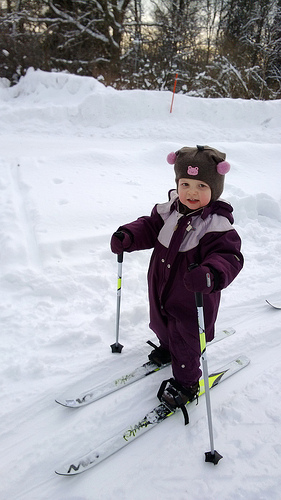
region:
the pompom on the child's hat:
[216, 161, 230, 175]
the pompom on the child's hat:
[166, 151, 176, 165]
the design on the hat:
[186, 164, 198, 174]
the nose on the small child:
[187, 187, 197, 196]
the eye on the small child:
[179, 181, 188, 186]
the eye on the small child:
[197, 183, 206, 187]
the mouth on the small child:
[186, 197, 198, 203]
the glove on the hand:
[182, 264, 213, 292]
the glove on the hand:
[109, 228, 129, 254]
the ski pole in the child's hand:
[189, 263, 222, 465]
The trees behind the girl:
[10, 0, 271, 97]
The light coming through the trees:
[111, 1, 241, 57]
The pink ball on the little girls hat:
[214, 155, 230, 172]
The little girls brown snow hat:
[164, 145, 234, 191]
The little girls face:
[182, 174, 212, 207]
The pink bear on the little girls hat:
[182, 165, 204, 179]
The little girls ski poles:
[190, 263, 231, 465]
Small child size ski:
[42, 306, 257, 472]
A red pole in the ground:
[169, 70, 181, 122]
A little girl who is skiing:
[31, 149, 255, 495]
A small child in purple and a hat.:
[109, 145, 244, 406]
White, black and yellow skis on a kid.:
[47, 325, 250, 475]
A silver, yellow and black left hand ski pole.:
[188, 260, 222, 465]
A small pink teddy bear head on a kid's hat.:
[188, 164, 200, 175]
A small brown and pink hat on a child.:
[165, 143, 230, 205]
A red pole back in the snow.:
[169, 70, 179, 113]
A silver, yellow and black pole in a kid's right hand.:
[109, 231, 124, 353]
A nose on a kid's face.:
[187, 183, 198, 195]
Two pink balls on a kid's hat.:
[166, 152, 229, 176]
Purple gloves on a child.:
[111, 230, 212, 292]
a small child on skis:
[54, 144, 248, 475]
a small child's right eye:
[181, 181, 191, 189]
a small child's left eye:
[196, 182, 206, 190]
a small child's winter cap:
[167, 142, 228, 202]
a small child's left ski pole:
[191, 263, 223, 467]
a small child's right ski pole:
[106, 234, 126, 351]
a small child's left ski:
[54, 353, 249, 476]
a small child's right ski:
[54, 325, 233, 410]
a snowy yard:
[0, 67, 280, 498]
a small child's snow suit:
[123, 188, 244, 382]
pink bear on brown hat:
[185, 165, 199, 176]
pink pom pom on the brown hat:
[214, 162, 230, 175]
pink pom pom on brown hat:
[164, 151, 176, 163]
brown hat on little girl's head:
[164, 146, 232, 176]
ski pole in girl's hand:
[188, 267, 221, 465]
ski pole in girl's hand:
[109, 229, 125, 356]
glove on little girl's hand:
[184, 264, 216, 291]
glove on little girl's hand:
[108, 229, 128, 253]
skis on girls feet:
[45, 354, 249, 474]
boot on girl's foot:
[159, 374, 196, 408]